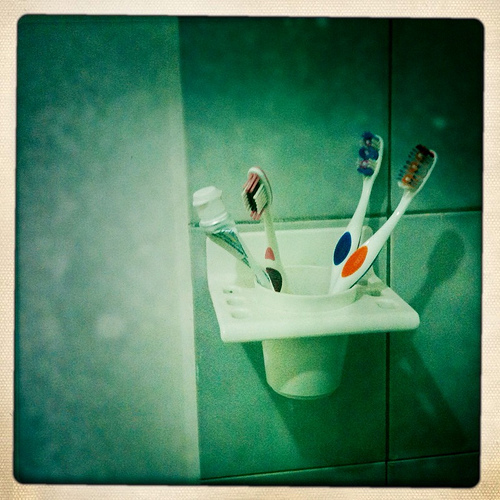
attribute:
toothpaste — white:
[182, 184, 266, 294]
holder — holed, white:
[195, 229, 416, 411]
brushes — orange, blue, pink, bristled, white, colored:
[237, 125, 440, 300]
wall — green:
[16, 12, 485, 496]